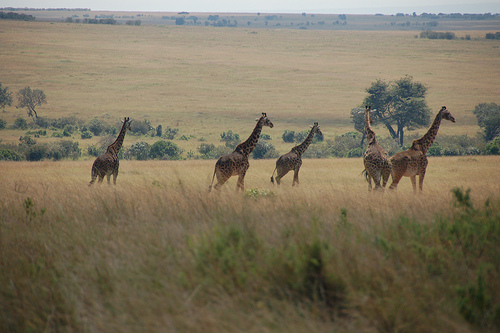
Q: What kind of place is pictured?
A: It is a plain.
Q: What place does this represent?
A: It represents the plain.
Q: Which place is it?
A: It is a plain.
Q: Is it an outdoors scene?
A: Yes, it is outdoors.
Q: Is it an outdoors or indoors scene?
A: It is outdoors.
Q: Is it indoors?
A: No, it is outdoors.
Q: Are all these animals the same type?
A: Yes, all the animals are giraffes.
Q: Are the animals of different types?
A: No, all the animals are giraffes.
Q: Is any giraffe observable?
A: Yes, there is a giraffe.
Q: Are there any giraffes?
A: Yes, there is a giraffe.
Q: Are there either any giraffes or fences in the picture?
A: Yes, there is a giraffe.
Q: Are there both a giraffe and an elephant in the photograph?
A: No, there is a giraffe but no elephants.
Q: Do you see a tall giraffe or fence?
A: Yes, there is a tall giraffe.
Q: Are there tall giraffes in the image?
A: Yes, there is a tall giraffe.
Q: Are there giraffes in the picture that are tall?
A: Yes, there is a giraffe that is tall.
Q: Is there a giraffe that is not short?
A: Yes, there is a tall giraffe.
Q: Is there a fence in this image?
A: No, there are no fences.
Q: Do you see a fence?
A: No, there are no fences.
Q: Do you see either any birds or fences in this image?
A: No, there are no fences or birds.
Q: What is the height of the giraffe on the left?
A: The giraffe is tall.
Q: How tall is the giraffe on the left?
A: The giraffe is tall.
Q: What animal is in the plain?
A: The animal is a giraffe.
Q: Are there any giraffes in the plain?
A: Yes, there is a giraffe in the plain.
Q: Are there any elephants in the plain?
A: No, there is a giraffe in the plain.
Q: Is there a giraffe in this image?
A: Yes, there is a giraffe.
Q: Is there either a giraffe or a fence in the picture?
A: Yes, there is a giraffe.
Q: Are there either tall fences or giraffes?
A: Yes, there is a tall giraffe.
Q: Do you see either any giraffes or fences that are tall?
A: Yes, the giraffe is tall.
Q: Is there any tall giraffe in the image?
A: Yes, there is a tall giraffe.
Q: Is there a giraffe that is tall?
A: Yes, there is a giraffe that is tall.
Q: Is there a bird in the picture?
A: No, there are no birds.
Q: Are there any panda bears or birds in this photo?
A: No, there are no birds or panda bears.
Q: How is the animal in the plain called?
A: The animal is a giraffe.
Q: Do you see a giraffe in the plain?
A: Yes, there is a giraffe in the plain.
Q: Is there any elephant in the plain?
A: No, there is a giraffe in the plain.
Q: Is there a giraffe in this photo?
A: Yes, there is a giraffe.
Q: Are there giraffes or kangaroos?
A: Yes, there is a giraffe.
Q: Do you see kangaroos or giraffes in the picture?
A: Yes, there is a giraffe.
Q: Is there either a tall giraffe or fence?
A: Yes, there is a tall giraffe.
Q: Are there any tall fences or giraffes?
A: Yes, there is a tall giraffe.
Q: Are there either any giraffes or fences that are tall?
A: Yes, the giraffe is tall.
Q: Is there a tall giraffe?
A: Yes, there is a tall giraffe.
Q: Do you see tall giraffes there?
A: Yes, there is a tall giraffe.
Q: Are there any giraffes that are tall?
A: Yes, there is a giraffe that is tall.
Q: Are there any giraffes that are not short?
A: Yes, there is a tall giraffe.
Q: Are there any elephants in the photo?
A: No, there are no elephants.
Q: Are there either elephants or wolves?
A: No, there are no elephants or wolves.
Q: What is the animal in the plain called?
A: The animal is a giraffe.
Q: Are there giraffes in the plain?
A: Yes, there is a giraffe in the plain.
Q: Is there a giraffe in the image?
A: Yes, there is a giraffe.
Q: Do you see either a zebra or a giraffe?
A: Yes, there is a giraffe.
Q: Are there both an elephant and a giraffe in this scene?
A: No, there is a giraffe but no elephants.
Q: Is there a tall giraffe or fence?
A: Yes, there is a tall giraffe.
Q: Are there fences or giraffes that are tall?
A: Yes, the giraffe is tall.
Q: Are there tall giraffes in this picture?
A: Yes, there is a tall giraffe.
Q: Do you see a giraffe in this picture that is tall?
A: Yes, there is a giraffe that is tall.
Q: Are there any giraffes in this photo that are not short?
A: Yes, there is a tall giraffe.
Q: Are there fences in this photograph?
A: No, there are no fences.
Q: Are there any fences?
A: No, there are no fences.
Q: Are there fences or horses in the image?
A: No, there are no fences or horses.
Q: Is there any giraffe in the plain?
A: Yes, there is a giraffe in the plain.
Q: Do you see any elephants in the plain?
A: No, there is a giraffe in the plain.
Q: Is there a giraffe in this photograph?
A: Yes, there is a giraffe.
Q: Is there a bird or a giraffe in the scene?
A: Yes, there is a giraffe.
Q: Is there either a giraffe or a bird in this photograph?
A: Yes, there is a giraffe.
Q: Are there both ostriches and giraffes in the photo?
A: No, there is a giraffe but no ostriches.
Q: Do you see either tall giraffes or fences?
A: Yes, there is a tall giraffe.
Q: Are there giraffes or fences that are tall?
A: Yes, the giraffe is tall.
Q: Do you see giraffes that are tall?
A: Yes, there is a tall giraffe.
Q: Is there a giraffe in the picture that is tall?
A: Yes, there is a giraffe that is tall.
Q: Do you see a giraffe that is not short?
A: Yes, there is a tall giraffe.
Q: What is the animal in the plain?
A: The animal is a giraffe.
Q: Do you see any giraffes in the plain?
A: Yes, there is a giraffe in the plain.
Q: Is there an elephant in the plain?
A: No, there is a giraffe in the plain.